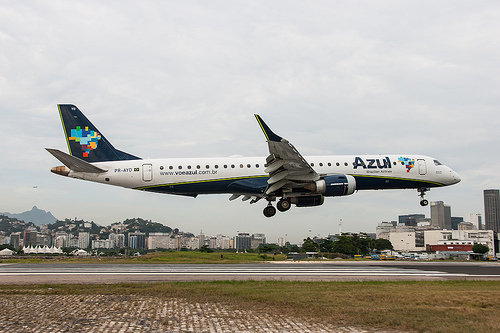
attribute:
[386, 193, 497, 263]
buildings — skyline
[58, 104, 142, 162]
tail — blue 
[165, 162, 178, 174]
window — small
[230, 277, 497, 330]
grass — yellow, green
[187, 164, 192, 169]
window — small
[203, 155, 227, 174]
window — small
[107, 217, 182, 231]
hill — three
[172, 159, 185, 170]
window — small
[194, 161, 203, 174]
window — small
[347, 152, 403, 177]
company — airline